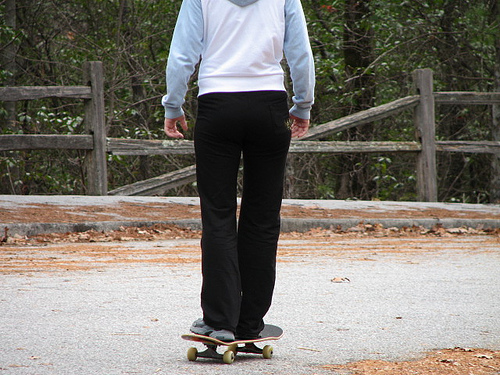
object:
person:
[160, 0, 314, 341]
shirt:
[162, 0, 317, 119]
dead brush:
[338, 348, 498, 373]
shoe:
[189, 318, 236, 341]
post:
[83, 60, 109, 196]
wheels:
[187, 347, 198, 361]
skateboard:
[181, 324, 284, 364]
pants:
[195, 91, 293, 337]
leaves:
[12, 230, 186, 244]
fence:
[0, 68, 500, 203]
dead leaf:
[330, 277, 350, 283]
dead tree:
[324, 2, 415, 198]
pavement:
[0, 197, 145, 220]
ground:
[4, 271, 149, 365]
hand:
[164, 115, 188, 139]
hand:
[289, 112, 310, 138]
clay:
[24, 210, 88, 224]